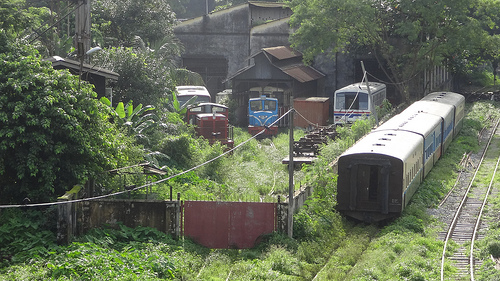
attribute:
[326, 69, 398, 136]
train car — white, striped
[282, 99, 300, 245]
pole — wooden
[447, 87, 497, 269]
tracks — gray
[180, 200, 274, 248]
fence — red, wooden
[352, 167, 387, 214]
door — open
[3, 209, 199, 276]
grass — tall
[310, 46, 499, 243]
train — old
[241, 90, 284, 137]
train — blue, red, white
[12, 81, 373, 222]
power line — hanging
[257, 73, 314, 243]
poles — wooden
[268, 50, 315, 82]
roof — brown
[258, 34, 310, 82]
roof — brown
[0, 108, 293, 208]
power line — electric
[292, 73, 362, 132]
power line — electric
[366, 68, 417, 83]
power line — electric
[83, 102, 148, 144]
leaves — green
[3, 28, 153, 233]
tree — green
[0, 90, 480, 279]
grass — green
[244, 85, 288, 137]
train engine — old, blue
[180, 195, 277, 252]
gate — red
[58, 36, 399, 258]
junk yard — rundown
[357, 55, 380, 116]
pole — leaning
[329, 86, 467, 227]
train — disabled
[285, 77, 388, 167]
train — disabled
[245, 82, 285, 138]
train — disabled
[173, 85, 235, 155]
train — disabled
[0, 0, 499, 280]
train yard — rundown